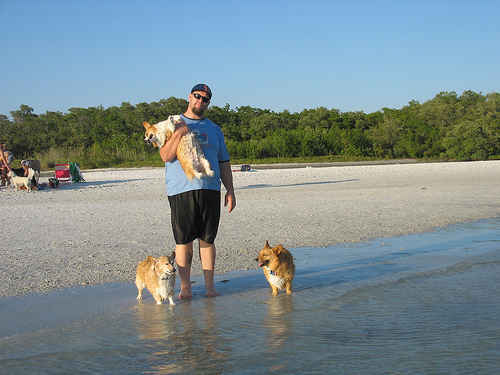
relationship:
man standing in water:
[157, 81, 239, 300] [4, 214, 500, 374]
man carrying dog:
[157, 81, 239, 300] [141, 113, 216, 181]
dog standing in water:
[255, 241, 299, 301] [4, 214, 500, 374]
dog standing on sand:
[128, 239, 179, 313] [3, 159, 500, 297]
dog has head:
[141, 113, 216, 181] [136, 116, 158, 146]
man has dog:
[157, 81, 239, 300] [141, 113, 216, 181]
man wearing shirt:
[157, 81, 239, 300] [163, 112, 231, 193]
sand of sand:
[3, 159, 500, 297] [0, 159, 500, 297]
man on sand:
[157, 81, 239, 300] [3, 159, 500, 297]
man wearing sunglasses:
[157, 81, 239, 300] [189, 90, 215, 105]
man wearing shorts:
[157, 81, 239, 300] [167, 188, 221, 245]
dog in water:
[255, 241, 299, 301] [4, 214, 500, 374]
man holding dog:
[157, 81, 239, 300] [141, 113, 216, 181]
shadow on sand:
[197, 236, 488, 290] [3, 159, 500, 297]